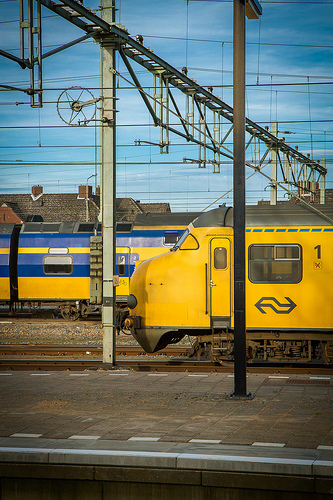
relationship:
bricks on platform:
[92, 372, 206, 434] [5, 369, 332, 452]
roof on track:
[313, 189, 333, 203] [18, 286, 300, 408]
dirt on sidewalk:
[34, 390, 220, 418] [15, 376, 279, 438]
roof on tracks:
[313, 189, 333, 203] [0, 336, 327, 372]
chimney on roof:
[76, 181, 91, 198] [131, 196, 170, 212]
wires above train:
[4, 3, 331, 186] [3, 217, 185, 315]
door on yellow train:
[206, 236, 231, 318] [124, 201, 331, 361]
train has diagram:
[0, 213, 331, 369] [252, 292, 298, 317]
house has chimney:
[0, 183, 168, 222] [79, 185, 91, 198]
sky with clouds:
[4, 0, 327, 194] [252, 48, 299, 89]